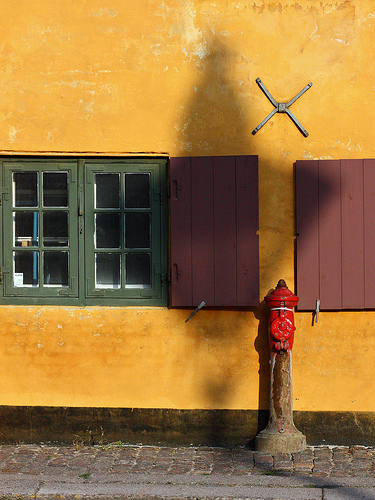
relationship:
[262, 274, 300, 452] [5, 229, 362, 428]
hydrant in front of building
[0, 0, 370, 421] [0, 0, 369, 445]
wall on side of building